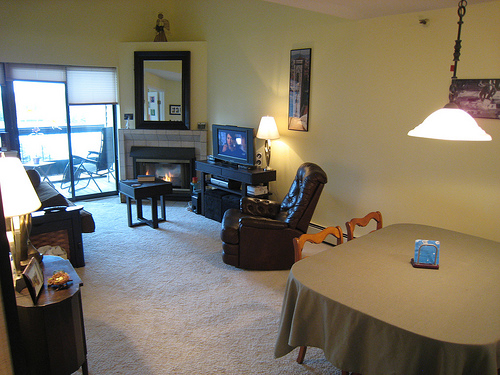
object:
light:
[406, 108, 493, 143]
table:
[271, 222, 499, 374]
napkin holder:
[410, 239, 440, 269]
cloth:
[273, 223, 500, 375]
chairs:
[292, 225, 343, 262]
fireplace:
[128, 146, 197, 203]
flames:
[163, 173, 172, 183]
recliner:
[220, 162, 328, 271]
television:
[212, 124, 254, 167]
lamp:
[255, 116, 280, 171]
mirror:
[143, 59, 183, 122]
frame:
[134, 51, 191, 131]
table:
[118, 176, 173, 229]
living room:
[1, 0, 353, 373]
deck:
[40, 168, 116, 199]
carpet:
[69, 193, 340, 375]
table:
[194, 158, 276, 223]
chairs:
[60, 127, 116, 193]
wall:
[116, 41, 209, 132]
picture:
[288, 48, 312, 132]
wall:
[209, 5, 499, 247]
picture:
[449, 78, 500, 118]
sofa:
[0, 168, 96, 269]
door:
[0, 64, 120, 201]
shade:
[406, 108, 492, 142]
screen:
[218, 129, 247, 159]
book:
[137, 175, 156, 181]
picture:
[27, 264, 43, 297]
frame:
[21, 256, 44, 305]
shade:
[255, 116, 280, 140]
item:
[47, 270, 73, 291]